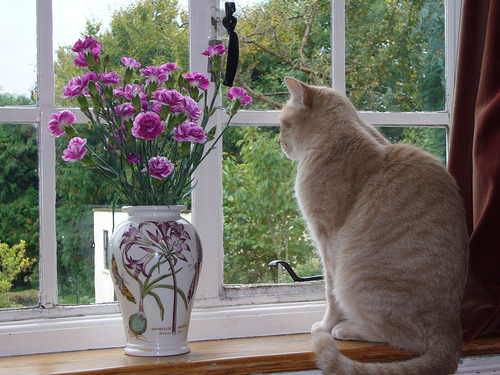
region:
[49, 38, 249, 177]
The purple flowers in the vase.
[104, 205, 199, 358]
The vase the flowers are in.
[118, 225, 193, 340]
The design on the vase.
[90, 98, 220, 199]
The stems of the flowers in the vase.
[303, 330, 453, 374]
The tail of the cat.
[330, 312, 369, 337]
The back foot of the cat.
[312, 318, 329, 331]
The front foot of the cat.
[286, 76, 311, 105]
The ear of the cat.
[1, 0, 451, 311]
The window the cat is looking out of.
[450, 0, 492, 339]
The brown curtain on the right.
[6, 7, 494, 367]
Photo taken during the day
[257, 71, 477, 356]
cat sitting on a window sill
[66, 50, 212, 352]
Vase of flowers on the window sill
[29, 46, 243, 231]
Flowers in a vase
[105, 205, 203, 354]
Flowers painted on the vase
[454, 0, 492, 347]
The curtain is open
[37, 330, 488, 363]
The window sill is brown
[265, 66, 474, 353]
The cat is light brown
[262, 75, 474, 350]
cat looking out the window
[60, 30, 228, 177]
The flowers are purple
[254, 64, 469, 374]
the cat on the window sill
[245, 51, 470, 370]
the cat is beige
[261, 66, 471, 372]
the cat is striped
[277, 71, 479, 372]
the cat looking outside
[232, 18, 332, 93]
the tree outside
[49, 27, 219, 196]
the flowers in the vase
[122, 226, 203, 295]
the flowers on the vase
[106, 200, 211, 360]
the vase on the window sill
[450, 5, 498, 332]
the curtain beside the cat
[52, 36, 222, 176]
the flowers are purple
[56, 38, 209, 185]
flowers in the vase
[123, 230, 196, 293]
flowers on the vase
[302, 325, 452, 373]
the tail of the cat